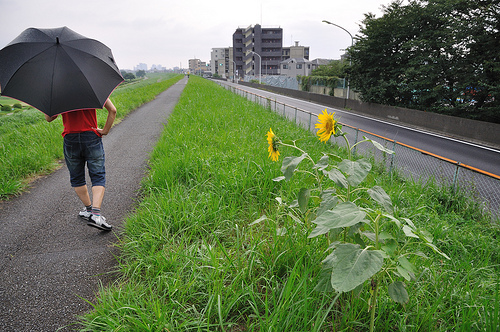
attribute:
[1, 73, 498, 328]
grass — green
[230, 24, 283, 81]
building — six story, distant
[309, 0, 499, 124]
trees — green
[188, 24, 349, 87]
buildings — distant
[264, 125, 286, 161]
sunflower — yellow, vibrant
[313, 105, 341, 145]
sunflower — yellow, vibrant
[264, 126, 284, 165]
sunflower — vibrant, yellow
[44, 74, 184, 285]
path — paved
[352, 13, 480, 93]
top — leafy, tree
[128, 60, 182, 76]
skyline — city's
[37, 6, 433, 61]
sky — overcast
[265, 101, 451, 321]
plant — yellow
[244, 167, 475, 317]
leaves — green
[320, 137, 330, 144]
petals — yellow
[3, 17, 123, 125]
umbrella — black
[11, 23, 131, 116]
umbrella — black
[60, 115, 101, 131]
shirt — red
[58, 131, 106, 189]
jean — knee length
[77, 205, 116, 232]
shoes — white, black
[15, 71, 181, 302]
path — asphalt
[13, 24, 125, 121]
umbrella — black, open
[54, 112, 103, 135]
t-shirt — red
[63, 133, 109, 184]
jeans — blue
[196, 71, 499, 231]
fence — chain link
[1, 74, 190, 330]
path — asphalt, paved, walking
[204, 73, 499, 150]
guard — concrete, wall